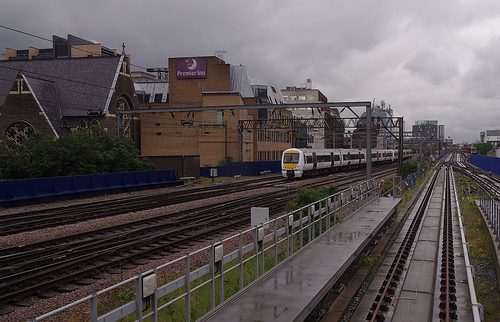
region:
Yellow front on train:
[266, 142, 324, 190]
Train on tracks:
[133, 174, 215, 320]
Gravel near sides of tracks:
[75, 218, 150, 288]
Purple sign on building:
[156, 42, 234, 116]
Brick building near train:
[75, 51, 222, 152]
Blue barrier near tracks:
[14, 164, 193, 191]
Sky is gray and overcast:
[284, 27, 450, 87]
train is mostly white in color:
[307, 134, 457, 171]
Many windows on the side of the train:
[297, 149, 402, 161]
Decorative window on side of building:
[3, 107, 57, 169]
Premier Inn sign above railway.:
[143, 49, 244, 94]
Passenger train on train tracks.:
[272, 140, 430, 177]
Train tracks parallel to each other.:
[1, 198, 283, 298]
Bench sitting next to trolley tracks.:
[223, 187, 409, 320]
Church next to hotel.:
[0, 17, 191, 161]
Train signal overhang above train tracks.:
[107, 78, 412, 190]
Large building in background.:
[372, 102, 473, 158]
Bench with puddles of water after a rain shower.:
[193, 191, 409, 320]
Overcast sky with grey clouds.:
[226, 2, 499, 131]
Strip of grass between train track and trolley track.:
[160, 163, 435, 320]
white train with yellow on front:
[22, 50, 437, 231]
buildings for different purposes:
[10, 31, 350, 191]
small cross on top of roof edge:
[105, 32, 135, 68]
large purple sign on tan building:
[161, 50, 221, 85]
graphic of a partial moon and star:
[161, 55, 207, 81]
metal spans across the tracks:
[95, 81, 405, 203]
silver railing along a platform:
[120, 160, 400, 315]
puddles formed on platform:
[210, 190, 410, 310]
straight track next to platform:
[345, 160, 472, 312]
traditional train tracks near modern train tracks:
[81, 172, 482, 312]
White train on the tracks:
[278, 139, 413, 180]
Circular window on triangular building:
[7, 119, 32, 154]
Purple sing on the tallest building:
[174, 55, 213, 86]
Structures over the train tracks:
[116, 97, 419, 179]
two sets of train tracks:
[0, 152, 393, 314]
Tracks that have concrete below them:
[364, 150, 496, 320]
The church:
[1, 40, 141, 160]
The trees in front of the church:
[8, 113, 150, 193]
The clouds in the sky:
[1, 0, 494, 141]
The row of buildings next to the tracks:
[0, 43, 451, 155]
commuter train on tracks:
[276, 135, 423, 190]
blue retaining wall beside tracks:
[4, 153, 275, 195]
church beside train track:
[5, 38, 160, 173]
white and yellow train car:
[273, 143, 338, 177]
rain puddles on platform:
[268, 213, 393, 318]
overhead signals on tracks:
[113, 93, 413, 180]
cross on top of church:
[108, 31, 136, 67]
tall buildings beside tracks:
[140, 55, 440, 157]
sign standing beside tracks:
[196, 159, 233, 194]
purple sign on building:
[168, 53, 215, 87]